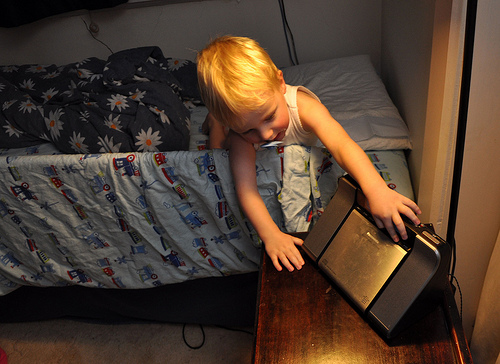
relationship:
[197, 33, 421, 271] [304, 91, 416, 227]
boy has arm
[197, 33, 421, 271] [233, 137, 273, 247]
boy has arm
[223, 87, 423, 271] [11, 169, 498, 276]
arms on front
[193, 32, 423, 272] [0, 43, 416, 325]
boy playing in h bed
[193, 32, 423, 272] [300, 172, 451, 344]
boy turning on radio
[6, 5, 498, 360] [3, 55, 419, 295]
room with bed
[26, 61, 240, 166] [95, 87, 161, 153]
blanket with pattern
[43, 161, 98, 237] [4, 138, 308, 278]
picture of blanket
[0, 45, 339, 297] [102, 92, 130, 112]
comforter with flowers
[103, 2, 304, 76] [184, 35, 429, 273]
pillow with toddler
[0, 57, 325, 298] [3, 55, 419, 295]
comforter in bed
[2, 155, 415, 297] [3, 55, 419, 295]
sheet on bed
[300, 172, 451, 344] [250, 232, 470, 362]
radio on table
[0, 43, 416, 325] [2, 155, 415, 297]
bed has sheet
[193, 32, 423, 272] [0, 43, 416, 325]
boy on bed